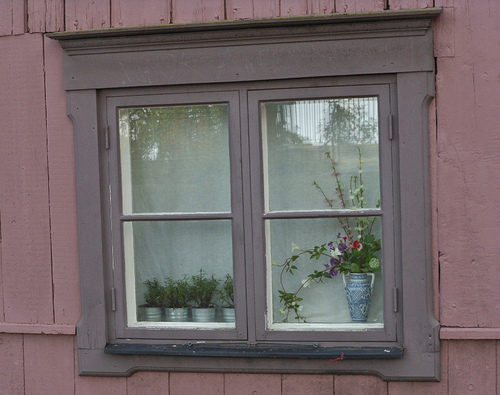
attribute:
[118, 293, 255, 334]
buckets — metal 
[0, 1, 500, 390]
house — red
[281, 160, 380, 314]
flowers — purple, red, white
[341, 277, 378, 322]
vase — blue, white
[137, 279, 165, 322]
plant — four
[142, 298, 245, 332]
can — small, metal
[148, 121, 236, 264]
curtain — white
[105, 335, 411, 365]
window — black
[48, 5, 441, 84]
wood — brown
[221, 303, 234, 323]
metal can — small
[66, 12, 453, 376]
window — brown, closed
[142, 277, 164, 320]
plant — small 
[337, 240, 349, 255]
flower — purple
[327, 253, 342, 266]
flower — purple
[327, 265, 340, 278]
flower — purple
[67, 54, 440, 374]
window — small 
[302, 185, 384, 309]
plant — green 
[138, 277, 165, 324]
plant — green 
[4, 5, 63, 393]
wood — purple